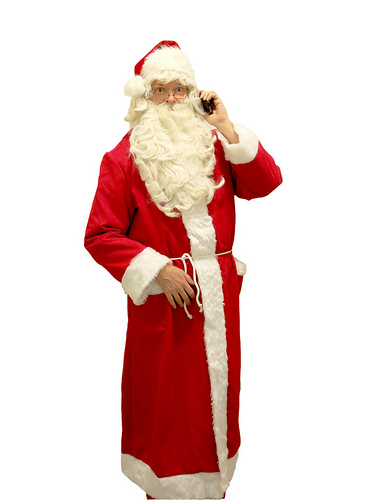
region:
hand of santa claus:
[158, 269, 206, 314]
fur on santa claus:
[209, 352, 221, 375]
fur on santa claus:
[218, 385, 223, 398]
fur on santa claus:
[170, 482, 188, 495]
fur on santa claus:
[138, 469, 153, 478]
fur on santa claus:
[220, 460, 232, 478]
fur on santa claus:
[156, 148, 171, 164]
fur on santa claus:
[132, 264, 147, 282]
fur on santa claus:
[223, 145, 241, 162]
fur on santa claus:
[184, 219, 209, 247]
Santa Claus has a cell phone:
[84, 40, 284, 496]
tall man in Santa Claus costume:
[83, 38, 283, 497]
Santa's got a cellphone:
[85, 38, 287, 497]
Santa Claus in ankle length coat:
[85, 39, 281, 495]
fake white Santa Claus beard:
[127, 90, 214, 213]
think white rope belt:
[162, 248, 231, 317]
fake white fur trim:
[120, 241, 168, 304]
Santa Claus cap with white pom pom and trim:
[125, 34, 193, 95]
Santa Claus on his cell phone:
[87, 39, 282, 495]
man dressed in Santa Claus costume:
[86, 38, 285, 497]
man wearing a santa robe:
[83, 34, 290, 498]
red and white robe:
[78, 122, 281, 498]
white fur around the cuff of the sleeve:
[116, 245, 168, 315]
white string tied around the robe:
[147, 240, 245, 324]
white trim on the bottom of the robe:
[112, 447, 256, 498]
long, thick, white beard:
[131, 105, 232, 223]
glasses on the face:
[151, 87, 193, 101]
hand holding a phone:
[186, 85, 231, 126]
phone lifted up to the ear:
[179, 82, 227, 114]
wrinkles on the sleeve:
[76, 154, 147, 283]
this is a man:
[114, 58, 276, 410]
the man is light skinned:
[165, 272, 180, 297]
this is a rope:
[204, 249, 228, 261]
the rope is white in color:
[196, 248, 219, 271]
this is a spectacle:
[154, 83, 192, 102]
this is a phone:
[198, 93, 215, 110]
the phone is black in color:
[201, 95, 217, 112]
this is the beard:
[159, 113, 200, 190]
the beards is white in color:
[163, 125, 187, 179]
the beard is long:
[164, 141, 208, 171]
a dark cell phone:
[199, 93, 217, 118]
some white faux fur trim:
[200, 295, 229, 493]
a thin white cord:
[148, 247, 233, 262]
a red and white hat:
[121, 36, 198, 92]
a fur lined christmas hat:
[120, 38, 202, 91]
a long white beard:
[126, 98, 226, 221]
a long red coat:
[85, 119, 282, 490]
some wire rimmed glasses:
[145, 90, 191, 100]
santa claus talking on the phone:
[80, 41, 282, 493]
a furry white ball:
[120, 74, 148, 101]